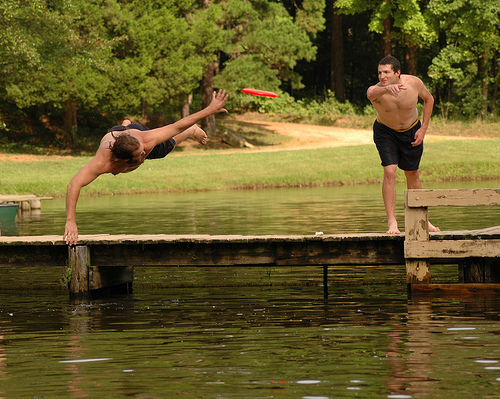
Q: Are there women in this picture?
A: No, there are no women.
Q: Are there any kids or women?
A: No, there are no women or kids.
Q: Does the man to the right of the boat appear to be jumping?
A: Yes, the man is jumping.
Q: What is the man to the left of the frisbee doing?
A: The man is jumping.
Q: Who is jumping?
A: The man is jumping.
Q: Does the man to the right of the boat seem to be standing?
A: No, the man is jumping.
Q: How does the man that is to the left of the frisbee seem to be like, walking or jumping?
A: The man is jumping.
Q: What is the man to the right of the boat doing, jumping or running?
A: The man is jumping.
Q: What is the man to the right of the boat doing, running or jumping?
A: The man is jumping.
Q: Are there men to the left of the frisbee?
A: Yes, there is a man to the left of the frisbee.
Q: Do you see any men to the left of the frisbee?
A: Yes, there is a man to the left of the frisbee.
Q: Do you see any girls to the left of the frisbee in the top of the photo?
A: No, there is a man to the left of the frisbee.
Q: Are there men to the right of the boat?
A: Yes, there is a man to the right of the boat.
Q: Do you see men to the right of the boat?
A: Yes, there is a man to the right of the boat.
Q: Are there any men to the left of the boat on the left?
A: No, the man is to the right of the boat.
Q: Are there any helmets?
A: No, there are no helmets.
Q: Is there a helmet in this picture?
A: No, there are no helmets.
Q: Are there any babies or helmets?
A: No, there are no helmets or babies.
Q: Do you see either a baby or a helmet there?
A: No, there are no helmets or babies.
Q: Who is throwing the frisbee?
A: The man is throwing the frisbee.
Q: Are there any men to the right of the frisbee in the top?
A: Yes, there is a man to the right of the frisbee.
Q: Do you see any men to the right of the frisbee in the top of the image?
A: Yes, there is a man to the right of the frisbee.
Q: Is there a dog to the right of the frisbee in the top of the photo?
A: No, there is a man to the right of the frisbee.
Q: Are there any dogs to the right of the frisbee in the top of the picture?
A: No, there is a man to the right of the frisbee.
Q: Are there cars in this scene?
A: No, there are no cars.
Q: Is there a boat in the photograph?
A: Yes, there is a boat.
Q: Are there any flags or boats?
A: Yes, there is a boat.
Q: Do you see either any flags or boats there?
A: Yes, there is a boat.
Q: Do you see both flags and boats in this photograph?
A: No, there is a boat but no flags.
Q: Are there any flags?
A: No, there are no flags.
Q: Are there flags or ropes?
A: No, there are no flags or ropes.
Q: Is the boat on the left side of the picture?
A: Yes, the boat is on the left of the image.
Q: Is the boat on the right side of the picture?
A: No, the boat is on the left of the image.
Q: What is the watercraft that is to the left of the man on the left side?
A: The watercraft is a boat.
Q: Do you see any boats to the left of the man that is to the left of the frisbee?
A: Yes, there is a boat to the left of the man.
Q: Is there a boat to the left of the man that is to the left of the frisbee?
A: Yes, there is a boat to the left of the man.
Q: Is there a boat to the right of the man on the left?
A: No, the boat is to the left of the man.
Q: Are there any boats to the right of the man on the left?
A: No, the boat is to the left of the man.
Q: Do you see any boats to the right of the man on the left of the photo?
A: No, the boat is to the left of the man.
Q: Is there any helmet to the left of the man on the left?
A: No, there is a boat to the left of the man.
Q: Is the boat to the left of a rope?
A: No, the boat is to the left of a man.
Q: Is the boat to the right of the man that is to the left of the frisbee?
A: No, the boat is to the left of the man.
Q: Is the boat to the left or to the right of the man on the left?
A: The boat is to the left of the man.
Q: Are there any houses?
A: No, there are no houses.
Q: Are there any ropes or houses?
A: No, there are no houses or ropes.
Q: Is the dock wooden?
A: Yes, the dock is wooden.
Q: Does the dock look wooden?
A: Yes, the dock is wooden.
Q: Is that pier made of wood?
A: Yes, the pier is made of wood.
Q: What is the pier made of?
A: The pier is made of wood.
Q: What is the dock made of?
A: The pier is made of wood.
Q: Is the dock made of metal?
A: No, the dock is made of wood.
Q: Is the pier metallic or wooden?
A: The pier is wooden.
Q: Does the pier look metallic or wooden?
A: The pier is wooden.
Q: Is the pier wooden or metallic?
A: The pier is wooden.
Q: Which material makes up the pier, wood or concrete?
A: The pier is made of wood.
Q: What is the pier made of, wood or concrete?
A: The pier is made of wood.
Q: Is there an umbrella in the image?
A: No, there are no umbrellas.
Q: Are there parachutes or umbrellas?
A: No, there are no umbrellas or parachutes.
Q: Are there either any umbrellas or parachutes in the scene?
A: No, there are no umbrellas or parachutes.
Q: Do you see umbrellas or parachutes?
A: No, there are no umbrellas or parachutes.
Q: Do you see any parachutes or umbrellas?
A: No, there are no umbrellas or parachutes.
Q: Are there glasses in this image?
A: No, there are no glasses.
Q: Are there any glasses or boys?
A: No, there are no glasses or boys.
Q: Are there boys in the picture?
A: No, there are no boys.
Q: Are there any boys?
A: No, there are no boys.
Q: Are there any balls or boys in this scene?
A: No, there are no boys or balls.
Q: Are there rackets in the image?
A: No, there are no rackets.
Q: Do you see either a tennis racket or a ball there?
A: No, there are no rackets or balls.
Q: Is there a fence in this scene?
A: Yes, there is a fence.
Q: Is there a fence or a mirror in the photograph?
A: Yes, there is a fence.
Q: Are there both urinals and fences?
A: No, there is a fence but no urinals.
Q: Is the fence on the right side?
A: Yes, the fence is on the right of the image.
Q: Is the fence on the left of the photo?
A: No, the fence is on the right of the image.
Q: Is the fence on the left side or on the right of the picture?
A: The fence is on the right of the image.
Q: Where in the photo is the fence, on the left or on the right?
A: The fence is on the right of the image.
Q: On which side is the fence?
A: The fence is on the right of the image.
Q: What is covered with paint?
A: The fence is covered with paint.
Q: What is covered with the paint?
A: The fence is covered with paint.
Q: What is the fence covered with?
A: The fence is covered with paint.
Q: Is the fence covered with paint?
A: Yes, the fence is covered with paint.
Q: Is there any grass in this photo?
A: Yes, there is grass.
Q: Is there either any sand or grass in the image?
A: Yes, there is grass.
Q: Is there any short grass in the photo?
A: Yes, there is short grass.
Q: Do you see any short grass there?
A: Yes, there is short grass.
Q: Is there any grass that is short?
A: Yes, there is grass that is short.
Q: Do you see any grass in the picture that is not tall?
A: Yes, there is short grass.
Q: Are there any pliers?
A: No, there are no pliers.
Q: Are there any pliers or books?
A: No, there are no pliers or books.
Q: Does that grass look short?
A: Yes, the grass is short.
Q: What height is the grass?
A: The grass is short.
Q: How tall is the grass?
A: The grass is short.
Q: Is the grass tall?
A: No, the grass is short.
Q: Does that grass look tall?
A: No, the grass is short.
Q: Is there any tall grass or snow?
A: No, there is grass but it is short.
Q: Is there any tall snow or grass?
A: No, there is grass but it is short.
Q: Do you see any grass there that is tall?
A: No, there is grass but it is short.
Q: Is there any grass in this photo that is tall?
A: No, there is grass but it is short.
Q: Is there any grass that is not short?
A: No, there is grass but it is short.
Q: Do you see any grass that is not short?
A: No, there is grass but it is short.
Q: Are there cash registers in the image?
A: No, there are no cash registers.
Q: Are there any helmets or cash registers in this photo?
A: No, there are no cash registers or helmets.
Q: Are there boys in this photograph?
A: No, there are no boys.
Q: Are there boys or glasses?
A: No, there are no boys or glasses.